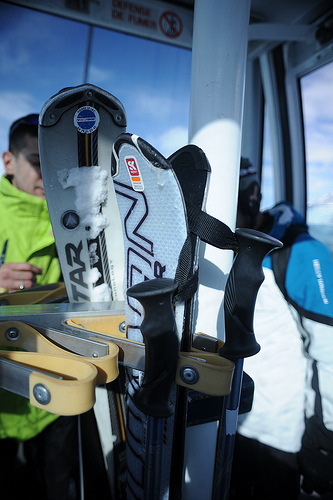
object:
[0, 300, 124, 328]
ski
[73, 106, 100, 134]
tag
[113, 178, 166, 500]
writing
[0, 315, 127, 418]
straps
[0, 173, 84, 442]
jacket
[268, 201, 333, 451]
jacket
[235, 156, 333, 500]
man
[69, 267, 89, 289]
letter a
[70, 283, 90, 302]
letter t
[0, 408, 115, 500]
color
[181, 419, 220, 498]
color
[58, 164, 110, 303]
snow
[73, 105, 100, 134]
border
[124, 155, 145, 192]
tag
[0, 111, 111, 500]
man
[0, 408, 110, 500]
pants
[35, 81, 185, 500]
skis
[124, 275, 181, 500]
pole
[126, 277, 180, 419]
grip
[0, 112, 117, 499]
he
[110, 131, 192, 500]
ski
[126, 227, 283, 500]
poles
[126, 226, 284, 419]
handles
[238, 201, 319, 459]
coat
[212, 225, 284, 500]
ski pole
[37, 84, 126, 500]
ski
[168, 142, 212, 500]
ski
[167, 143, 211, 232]
bottom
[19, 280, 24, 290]
ring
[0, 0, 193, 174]
sky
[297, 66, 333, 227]
sky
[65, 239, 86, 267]
letter